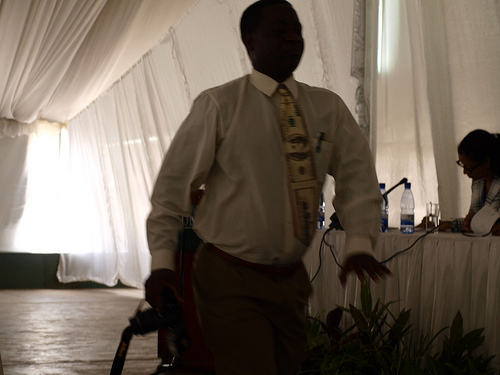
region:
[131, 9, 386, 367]
man dancing at wedding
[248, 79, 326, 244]
hundred dollar bill tie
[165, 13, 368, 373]
man wearing a tie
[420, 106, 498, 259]
woman with glasses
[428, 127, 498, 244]
woman at a table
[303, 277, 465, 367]
plants by a table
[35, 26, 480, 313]
large white draped tent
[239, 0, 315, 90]
blad mans head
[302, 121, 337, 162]
stuff in front pocket on a white shirt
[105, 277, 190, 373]
cane next to a man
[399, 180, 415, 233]
a plastic bottle of natural water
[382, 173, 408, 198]
an audio microphone on the table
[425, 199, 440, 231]
a clear water glass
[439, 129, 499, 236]
a lady sitting at an event table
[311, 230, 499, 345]
an event table with a white table cloth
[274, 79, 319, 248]
a yellow neck tie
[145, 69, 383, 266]
the man is wearing a white dress shirt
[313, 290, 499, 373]
some plants in a planter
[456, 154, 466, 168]
a lady is wearing eye glasses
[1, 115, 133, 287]
sunlight coming through the window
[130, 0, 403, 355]
man walking in room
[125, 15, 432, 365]
man dancing on floor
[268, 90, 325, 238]
neck tie on man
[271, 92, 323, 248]
neck tie with money on it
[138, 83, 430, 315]
white long sleeve button up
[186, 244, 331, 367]
tan dress pants on man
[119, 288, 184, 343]
black camera in man's hand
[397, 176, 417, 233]
bottle of water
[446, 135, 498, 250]
person writing at table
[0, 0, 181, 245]
white curtains everywhere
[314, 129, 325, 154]
A pen in the shirt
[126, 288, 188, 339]
A camera in the hand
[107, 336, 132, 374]
A black camera strap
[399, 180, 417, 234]
A water bottle on the table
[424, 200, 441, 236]
A glass of water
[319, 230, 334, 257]
Black microphone cables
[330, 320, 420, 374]
Green plants on the floor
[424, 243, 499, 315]
A white table cloth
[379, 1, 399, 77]
Light shining through the curtain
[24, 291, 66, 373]
Light reflecting on the floor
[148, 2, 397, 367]
the man standing in front of the table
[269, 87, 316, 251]
the tie around the man's neck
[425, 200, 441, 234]
the clear glass on the table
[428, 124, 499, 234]
the person at the table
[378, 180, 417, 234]
the water bottles on the table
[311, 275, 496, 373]
the plants in front of the table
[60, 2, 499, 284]
the white curtains hanging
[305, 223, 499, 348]
the white table cloth on the table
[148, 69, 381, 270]
the white long sleeved shirt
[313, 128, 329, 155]
the objects in the man's pocket